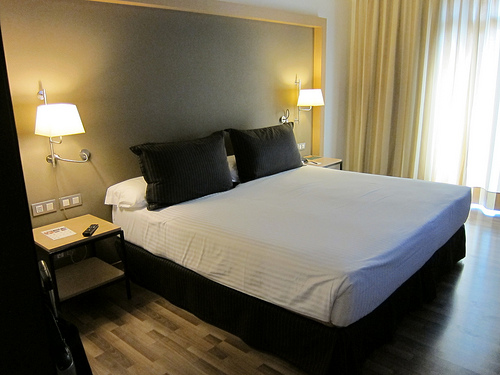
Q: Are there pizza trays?
A: No, there are no pizza trays.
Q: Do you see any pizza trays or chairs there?
A: No, there are no pizza trays or chairs.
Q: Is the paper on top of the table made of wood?
A: Yes, the paper is on top of the table.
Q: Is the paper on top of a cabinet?
A: No, the paper is on top of the table.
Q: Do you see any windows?
A: Yes, there is a window.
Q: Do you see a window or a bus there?
A: Yes, there is a window.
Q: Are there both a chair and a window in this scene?
A: No, there is a window but no chairs.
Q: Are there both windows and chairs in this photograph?
A: No, there is a window but no chairs.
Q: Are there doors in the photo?
A: No, there are no doors.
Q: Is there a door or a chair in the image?
A: No, there are no doors or chairs.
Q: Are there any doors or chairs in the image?
A: No, there are no doors or chairs.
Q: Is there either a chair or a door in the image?
A: No, there are no doors or chairs.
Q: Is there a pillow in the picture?
A: Yes, there is a pillow.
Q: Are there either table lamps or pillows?
A: Yes, there is a pillow.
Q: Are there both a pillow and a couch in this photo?
A: No, there is a pillow but no couches.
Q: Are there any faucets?
A: No, there are no faucets.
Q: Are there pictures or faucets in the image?
A: No, there are no faucets or pictures.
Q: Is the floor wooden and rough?
A: No, the floor is wooden but smooth.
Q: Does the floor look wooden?
A: Yes, the floor is wooden.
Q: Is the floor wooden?
A: Yes, the floor is wooden.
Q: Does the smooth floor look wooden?
A: Yes, the floor is wooden.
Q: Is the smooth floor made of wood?
A: Yes, the floor is made of wood.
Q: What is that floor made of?
A: The floor is made of wood.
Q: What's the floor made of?
A: The floor is made of wood.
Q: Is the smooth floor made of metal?
A: No, the floor is made of wood.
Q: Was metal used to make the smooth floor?
A: No, the floor is made of wood.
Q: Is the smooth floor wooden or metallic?
A: The floor is wooden.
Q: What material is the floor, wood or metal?
A: The floor is made of wood.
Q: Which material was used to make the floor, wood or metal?
A: The floor is made of wood.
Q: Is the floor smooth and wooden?
A: Yes, the floor is smooth and wooden.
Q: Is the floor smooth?
A: Yes, the floor is smooth.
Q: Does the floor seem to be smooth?
A: Yes, the floor is smooth.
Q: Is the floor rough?
A: No, the floor is smooth.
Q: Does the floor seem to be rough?
A: No, the floor is smooth.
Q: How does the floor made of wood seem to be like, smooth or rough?
A: The floor is smooth.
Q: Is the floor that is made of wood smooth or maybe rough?
A: The floor is smooth.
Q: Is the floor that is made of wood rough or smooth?
A: The floor is smooth.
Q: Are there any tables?
A: Yes, there is a table.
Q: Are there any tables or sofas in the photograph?
A: Yes, there is a table.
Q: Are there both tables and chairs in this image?
A: No, there is a table but no chairs.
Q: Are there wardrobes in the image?
A: No, there are no wardrobes.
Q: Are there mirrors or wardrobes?
A: No, there are no wardrobes or mirrors.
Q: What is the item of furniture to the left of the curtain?
A: The piece of furniture is a table.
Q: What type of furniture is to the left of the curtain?
A: The piece of furniture is a table.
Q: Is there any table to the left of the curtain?
A: Yes, there is a table to the left of the curtain.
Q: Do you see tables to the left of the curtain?
A: Yes, there is a table to the left of the curtain.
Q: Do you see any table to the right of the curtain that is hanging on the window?
A: No, the table is to the left of the curtain.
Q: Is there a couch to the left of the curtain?
A: No, there is a table to the left of the curtain.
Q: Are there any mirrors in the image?
A: No, there are no mirrors.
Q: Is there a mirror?
A: No, there are no mirrors.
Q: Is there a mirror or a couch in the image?
A: No, there are no mirrors or couches.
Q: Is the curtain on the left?
A: No, the curtain is on the right of the image.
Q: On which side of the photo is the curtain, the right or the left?
A: The curtain is on the right of the image.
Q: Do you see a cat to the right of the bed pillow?
A: No, there is a curtain to the right of the pillow.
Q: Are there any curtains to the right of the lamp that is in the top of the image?
A: Yes, there is a curtain to the right of the lamp.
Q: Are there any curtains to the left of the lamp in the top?
A: No, the curtain is to the right of the lamp.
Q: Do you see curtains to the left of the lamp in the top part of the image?
A: No, the curtain is to the right of the lamp.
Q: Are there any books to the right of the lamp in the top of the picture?
A: No, there is a curtain to the right of the lamp.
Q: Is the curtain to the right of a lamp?
A: Yes, the curtain is to the right of a lamp.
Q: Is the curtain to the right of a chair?
A: No, the curtain is to the right of a lamp.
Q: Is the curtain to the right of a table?
A: Yes, the curtain is to the right of a table.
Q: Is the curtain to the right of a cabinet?
A: No, the curtain is to the right of a table.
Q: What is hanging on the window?
A: The curtain is hanging on the window.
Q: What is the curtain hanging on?
A: The curtain is hanging on the window.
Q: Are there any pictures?
A: No, there are no pictures.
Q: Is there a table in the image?
A: Yes, there is a table.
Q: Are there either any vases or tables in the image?
A: Yes, there is a table.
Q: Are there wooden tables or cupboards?
A: Yes, there is a wood table.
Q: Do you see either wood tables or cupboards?
A: Yes, there is a wood table.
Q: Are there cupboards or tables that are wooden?
A: Yes, the table is wooden.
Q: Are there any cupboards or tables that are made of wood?
A: Yes, the table is made of wood.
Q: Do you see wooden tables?
A: Yes, there is a wood table.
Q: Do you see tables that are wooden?
A: Yes, there is a table that is wooden.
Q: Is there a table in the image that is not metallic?
A: Yes, there is a wooden table.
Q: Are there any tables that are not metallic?
A: Yes, there is a wooden table.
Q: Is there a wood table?
A: Yes, there is a table that is made of wood.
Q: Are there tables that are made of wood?
A: Yes, there is a table that is made of wood.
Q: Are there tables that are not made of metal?
A: Yes, there is a table that is made of wood.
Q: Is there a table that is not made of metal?
A: Yes, there is a table that is made of wood.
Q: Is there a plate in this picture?
A: No, there are no plates.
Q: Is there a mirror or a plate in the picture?
A: No, there are no plates or mirrors.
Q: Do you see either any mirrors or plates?
A: No, there are no plates or mirrors.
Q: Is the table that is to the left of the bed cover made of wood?
A: Yes, the table is made of wood.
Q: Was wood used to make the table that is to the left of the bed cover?
A: Yes, the table is made of wood.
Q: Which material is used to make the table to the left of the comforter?
A: The table is made of wood.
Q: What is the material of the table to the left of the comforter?
A: The table is made of wood.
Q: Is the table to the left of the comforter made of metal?
A: No, the table is made of wood.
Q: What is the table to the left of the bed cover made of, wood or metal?
A: The table is made of wood.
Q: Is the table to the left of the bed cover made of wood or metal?
A: The table is made of wood.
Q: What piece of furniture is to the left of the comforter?
A: The piece of furniture is a table.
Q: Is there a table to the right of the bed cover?
A: No, the table is to the left of the bed cover.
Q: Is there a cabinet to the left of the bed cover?
A: No, there is a table to the left of the bed cover.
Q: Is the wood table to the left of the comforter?
A: Yes, the table is to the left of the comforter.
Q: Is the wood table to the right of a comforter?
A: No, the table is to the left of a comforter.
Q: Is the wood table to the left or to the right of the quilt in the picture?
A: The table is to the left of the quilt.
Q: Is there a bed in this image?
A: Yes, there is a bed.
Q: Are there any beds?
A: Yes, there is a bed.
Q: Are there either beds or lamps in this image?
A: Yes, there is a bed.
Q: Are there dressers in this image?
A: No, there are no dressers.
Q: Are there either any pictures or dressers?
A: No, there are no dressers or pictures.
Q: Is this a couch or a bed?
A: This is a bed.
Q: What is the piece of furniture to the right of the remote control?
A: The piece of furniture is a bed.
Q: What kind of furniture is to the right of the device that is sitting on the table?
A: The piece of furniture is a bed.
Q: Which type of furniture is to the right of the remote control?
A: The piece of furniture is a bed.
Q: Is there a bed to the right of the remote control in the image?
A: Yes, there is a bed to the right of the remote control.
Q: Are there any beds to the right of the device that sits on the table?
A: Yes, there is a bed to the right of the remote control.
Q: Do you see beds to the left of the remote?
A: No, the bed is to the right of the remote.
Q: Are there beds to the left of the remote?
A: No, the bed is to the right of the remote.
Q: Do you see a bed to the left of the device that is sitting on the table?
A: No, the bed is to the right of the remote.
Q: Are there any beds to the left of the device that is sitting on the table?
A: No, the bed is to the right of the remote.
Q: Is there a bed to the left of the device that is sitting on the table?
A: No, the bed is to the right of the remote.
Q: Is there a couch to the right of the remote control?
A: No, there is a bed to the right of the remote control.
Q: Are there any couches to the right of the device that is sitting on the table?
A: No, there is a bed to the right of the remote control.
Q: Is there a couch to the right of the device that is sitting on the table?
A: No, there is a bed to the right of the remote control.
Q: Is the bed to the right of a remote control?
A: Yes, the bed is to the right of a remote control.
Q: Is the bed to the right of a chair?
A: No, the bed is to the right of a remote control.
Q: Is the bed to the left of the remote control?
A: No, the bed is to the right of the remote control.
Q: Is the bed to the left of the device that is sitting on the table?
A: No, the bed is to the right of the remote control.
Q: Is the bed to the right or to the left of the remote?
A: The bed is to the right of the remote.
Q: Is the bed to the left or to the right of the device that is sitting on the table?
A: The bed is to the right of the remote.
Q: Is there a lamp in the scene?
A: Yes, there is a lamp.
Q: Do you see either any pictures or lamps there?
A: Yes, there is a lamp.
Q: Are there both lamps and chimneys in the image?
A: No, there is a lamp but no chimneys.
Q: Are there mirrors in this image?
A: No, there are no mirrors.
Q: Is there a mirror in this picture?
A: No, there are no mirrors.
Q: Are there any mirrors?
A: No, there are no mirrors.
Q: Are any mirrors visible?
A: No, there are no mirrors.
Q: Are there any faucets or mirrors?
A: No, there are no mirrors or faucets.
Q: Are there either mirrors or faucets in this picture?
A: No, there are no mirrors or faucets.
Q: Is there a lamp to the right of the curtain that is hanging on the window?
A: No, the lamp is to the left of the curtain.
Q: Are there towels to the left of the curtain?
A: No, there is a lamp to the left of the curtain.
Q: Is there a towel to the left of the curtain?
A: No, there is a lamp to the left of the curtain.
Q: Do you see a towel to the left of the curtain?
A: No, there is a lamp to the left of the curtain.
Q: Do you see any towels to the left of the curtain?
A: No, there is a lamp to the left of the curtain.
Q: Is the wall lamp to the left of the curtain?
A: Yes, the lamp is to the left of the curtain.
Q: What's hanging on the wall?
A: The lamp is hanging on the wall.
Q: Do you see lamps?
A: Yes, there is a lamp.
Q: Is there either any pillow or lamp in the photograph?
A: Yes, there is a lamp.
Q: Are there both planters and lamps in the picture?
A: No, there is a lamp but no planters.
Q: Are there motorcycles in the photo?
A: No, there are no motorcycles.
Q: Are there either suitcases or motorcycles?
A: No, there are no motorcycles or suitcases.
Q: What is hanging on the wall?
A: The lamp is hanging on the wall.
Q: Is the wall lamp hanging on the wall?
A: Yes, the lamp is hanging on the wall.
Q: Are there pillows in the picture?
A: Yes, there is a pillow.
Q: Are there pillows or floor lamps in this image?
A: Yes, there is a pillow.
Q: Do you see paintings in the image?
A: No, there are no paintings.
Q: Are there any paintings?
A: No, there are no paintings.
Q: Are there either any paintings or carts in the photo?
A: No, there are no paintings or carts.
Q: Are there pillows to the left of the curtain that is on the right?
A: Yes, there is a pillow to the left of the curtain.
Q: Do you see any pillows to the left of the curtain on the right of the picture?
A: Yes, there is a pillow to the left of the curtain.